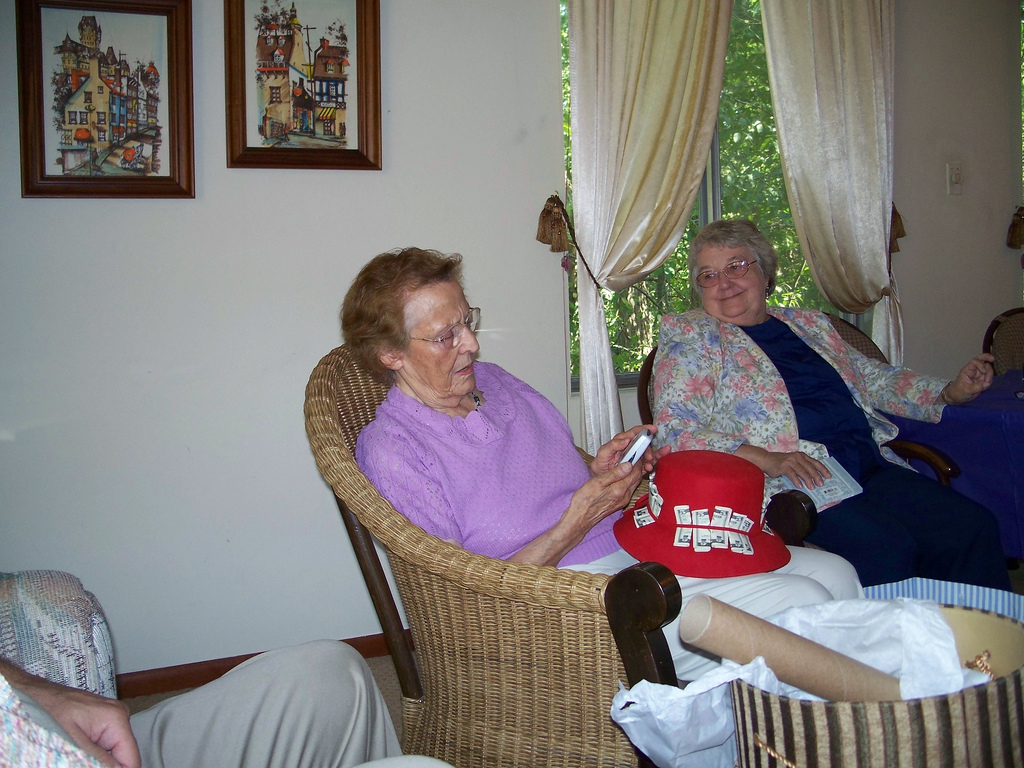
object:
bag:
[733, 660, 1024, 765]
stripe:
[734, 685, 766, 767]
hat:
[613, 448, 789, 578]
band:
[674, 503, 754, 553]